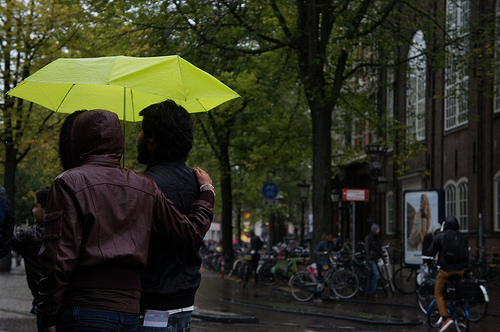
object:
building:
[310, 0, 499, 295]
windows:
[441, 113, 464, 132]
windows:
[383, 187, 396, 237]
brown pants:
[432, 267, 469, 317]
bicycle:
[286, 248, 360, 302]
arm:
[154, 180, 216, 247]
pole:
[298, 202, 306, 248]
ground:
[0, 250, 499, 332]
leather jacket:
[31, 106, 221, 322]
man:
[134, 96, 207, 330]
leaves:
[250, 65, 285, 90]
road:
[0, 250, 499, 332]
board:
[401, 187, 441, 266]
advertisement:
[401, 188, 444, 268]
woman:
[407, 192, 432, 251]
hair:
[137, 98, 196, 166]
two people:
[21, 95, 219, 331]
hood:
[57, 108, 126, 171]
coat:
[425, 214, 470, 273]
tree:
[0, 0, 499, 277]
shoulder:
[123, 164, 156, 187]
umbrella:
[4, 53, 243, 166]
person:
[419, 216, 472, 332]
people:
[33, 109, 221, 331]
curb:
[198, 291, 424, 326]